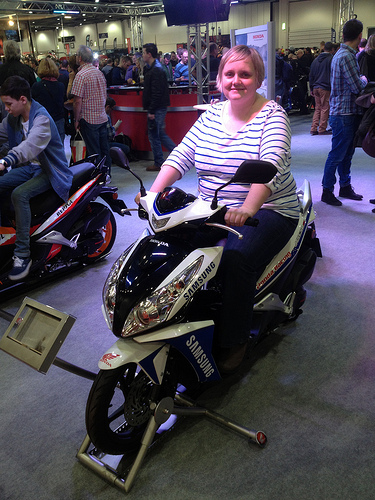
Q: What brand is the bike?
A: Samsung.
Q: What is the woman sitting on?
A: Motorcycle.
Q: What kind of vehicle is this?
A: Motorcycle.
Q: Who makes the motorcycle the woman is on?
A: Samsung.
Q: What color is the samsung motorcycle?
A: Silver, white and dark blue.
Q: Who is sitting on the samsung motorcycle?
A: Woman in black and white shirt.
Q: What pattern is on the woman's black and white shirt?
A: Thin stripes.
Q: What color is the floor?
A: Grey.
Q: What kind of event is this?
A: Convention.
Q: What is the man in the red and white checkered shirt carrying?
A: Shopping bag.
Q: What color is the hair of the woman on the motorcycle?
A: Blonde.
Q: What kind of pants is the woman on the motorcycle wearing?
A: Jeans.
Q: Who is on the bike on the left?
A: A boy.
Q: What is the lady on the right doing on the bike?
A: Trying out the new Samsung bike.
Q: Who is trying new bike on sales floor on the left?
A: A man.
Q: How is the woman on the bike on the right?
A: Blonde in white and blue striped shirt.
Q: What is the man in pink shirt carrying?
A: A bag.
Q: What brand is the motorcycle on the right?
A: Samsung.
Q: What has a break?
A: Motorcycle.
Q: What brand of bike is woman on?
A: Samsung.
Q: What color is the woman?
A: White.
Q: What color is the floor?
A: Gray.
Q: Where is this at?
A: A bike show.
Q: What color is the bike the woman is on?
A: Gray and black.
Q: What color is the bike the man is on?
A: Red.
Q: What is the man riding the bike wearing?
A: Jacket.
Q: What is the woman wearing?
A: A striped shirt.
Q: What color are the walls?
A: White.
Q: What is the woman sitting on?
A: A motorcycle.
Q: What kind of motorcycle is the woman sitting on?
A: Samsung.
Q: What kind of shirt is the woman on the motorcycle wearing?
A: Blue and white striped.